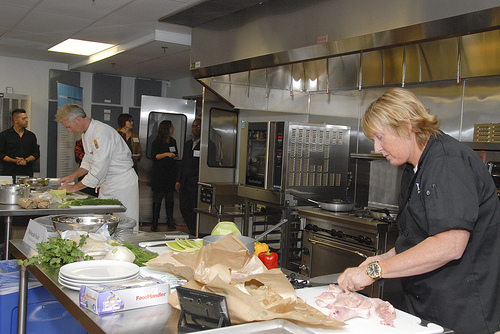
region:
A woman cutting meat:
[333, 85, 499, 331]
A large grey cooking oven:
[236, 115, 356, 212]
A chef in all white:
[44, 100, 146, 234]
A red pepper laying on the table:
[256, 246, 287, 273]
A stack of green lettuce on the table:
[18, 233, 97, 265]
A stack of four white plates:
[52, 257, 146, 290]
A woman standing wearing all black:
[147, 112, 183, 237]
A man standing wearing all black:
[1, 107, 43, 180]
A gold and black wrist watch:
[362, 258, 389, 288]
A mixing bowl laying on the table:
[202, 216, 287, 257]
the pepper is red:
[262, 254, 277, 268]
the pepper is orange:
[256, 241, 266, 253]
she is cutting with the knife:
[307, 271, 359, 292]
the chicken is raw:
[317, 289, 359, 317]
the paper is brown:
[223, 261, 252, 298]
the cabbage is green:
[216, 219, 235, 239]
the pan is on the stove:
[319, 197, 356, 216]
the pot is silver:
[3, 183, 16, 205]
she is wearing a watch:
[361, 258, 385, 283]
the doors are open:
[135, 89, 208, 210]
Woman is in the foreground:
[324, 64, 490, 332]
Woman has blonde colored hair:
[341, 79, 449, 183]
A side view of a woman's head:
[356, 82, 446, 177]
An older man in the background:
[41, 92, 147, 232]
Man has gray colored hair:
[52, 101, 92, 138]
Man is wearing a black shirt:
[2, 97, 42, 182]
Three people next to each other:
[116, 103, 202, 229]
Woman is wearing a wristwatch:
[356, 246, 381, 281]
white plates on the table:
[50, 260, 146, 290]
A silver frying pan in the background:
[285, 181, 361, 227]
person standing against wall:
[107, 113, 179, 218]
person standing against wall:
[6, 114, 43, 174]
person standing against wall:
[137, 120, 176, 225]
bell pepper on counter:
[250, 245, 283, 260]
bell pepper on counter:
[250, 240, 275, 253]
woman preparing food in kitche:
[358, 92, 493, 330]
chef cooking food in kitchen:
[55, 115, 135, 221]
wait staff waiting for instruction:
[143, 115, 178, 218]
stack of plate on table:
[75, 255, 137, 272]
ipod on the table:
[166, 279, 237, 324]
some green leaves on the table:
[32, 245, 59, 262]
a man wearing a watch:
[362, 266, 391, 295]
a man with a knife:
[310, 257, 344, 287]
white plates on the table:
[81, 263, 119, 292]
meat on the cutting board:
[319, 286, 351, 308]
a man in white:
[91, 165, 112, 181]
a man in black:
[404, 189, 436, 232]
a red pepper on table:
[263, 245, 274, 264]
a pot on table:
[10, 184, 33, 197]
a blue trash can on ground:
[5, 266, 45, 293]